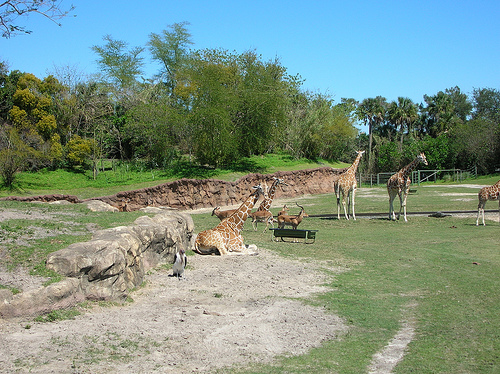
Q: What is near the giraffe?
A: Stone ledge.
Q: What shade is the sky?
A: Deep blue.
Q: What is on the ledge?
A: Grass.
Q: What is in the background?
A: Trees.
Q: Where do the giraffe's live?
A: The zoo.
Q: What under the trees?
A: Green grass.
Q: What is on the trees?
A: Green leaves.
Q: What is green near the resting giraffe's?
A: A bench.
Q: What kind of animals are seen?
A: Giraffes.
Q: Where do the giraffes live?
A: Zoo.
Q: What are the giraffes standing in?
A: Grass.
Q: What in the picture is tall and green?
A: Trees.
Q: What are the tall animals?
A: Giraffes.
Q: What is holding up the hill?
A: Rocks.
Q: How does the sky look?
A: Clear.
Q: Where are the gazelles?
A: In the grass.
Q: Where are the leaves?
A: On the trees.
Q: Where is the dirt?
A: On the ground.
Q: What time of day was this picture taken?
A: Daytime.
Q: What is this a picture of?
A: Animals.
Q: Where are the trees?
A: The background.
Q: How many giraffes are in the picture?
A: Five.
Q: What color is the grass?
A: Green.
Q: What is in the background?
A: Trees.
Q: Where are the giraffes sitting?
A: The ground.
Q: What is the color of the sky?
A: Blue.